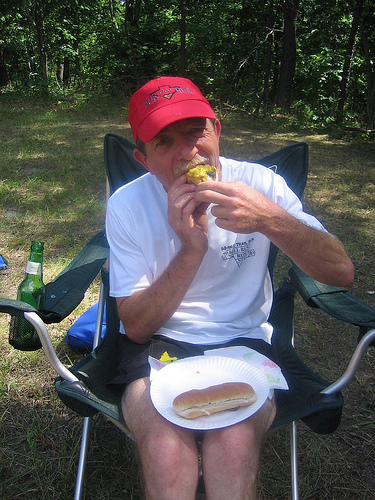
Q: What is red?
A: Hat.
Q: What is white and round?
A: Paper plate.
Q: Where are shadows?
A: On the grass.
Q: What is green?
A: Bottle.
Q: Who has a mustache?
A: The man.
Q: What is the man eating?
A: A hot dog.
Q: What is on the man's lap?
A: A plate.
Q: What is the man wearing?
A: A shirt.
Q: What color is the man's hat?
A: Red.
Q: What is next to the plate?
A: A paper towel.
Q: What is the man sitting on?
A: A chair.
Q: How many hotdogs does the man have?
A: Two.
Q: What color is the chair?
A: Black.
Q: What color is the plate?
A: White.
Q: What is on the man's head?
A: A baseball cap.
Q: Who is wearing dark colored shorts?
A: The man.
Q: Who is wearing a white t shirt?
A: The man.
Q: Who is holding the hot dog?
A: The man.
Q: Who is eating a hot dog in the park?
A: The man.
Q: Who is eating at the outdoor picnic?
A: The man.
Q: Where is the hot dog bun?
A: On the plate.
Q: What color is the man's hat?
A: Red.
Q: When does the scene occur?
A: Daytime.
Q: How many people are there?
A: One.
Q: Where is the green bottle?
A: In the chair's cup holder.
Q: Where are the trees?
A: Behind the man.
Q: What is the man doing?
A: Eating a hot dog.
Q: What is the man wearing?
A: A white shirt and shorts.